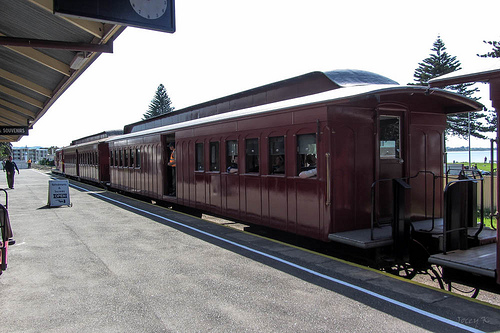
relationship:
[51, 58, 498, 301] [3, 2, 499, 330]
train stopped at station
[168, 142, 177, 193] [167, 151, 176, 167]
man has vest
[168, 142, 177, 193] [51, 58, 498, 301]
man standing on train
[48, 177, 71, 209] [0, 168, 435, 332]
sign sitting on ground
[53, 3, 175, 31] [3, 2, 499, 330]
clock hanging at station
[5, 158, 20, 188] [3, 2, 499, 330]
man walking at station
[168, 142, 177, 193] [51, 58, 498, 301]
man on train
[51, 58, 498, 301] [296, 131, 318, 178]
train has window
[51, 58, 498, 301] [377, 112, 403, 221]
train has door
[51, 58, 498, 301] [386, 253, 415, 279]
train has wheel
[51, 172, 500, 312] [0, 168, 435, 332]
line painted on ground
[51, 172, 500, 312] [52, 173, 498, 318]
line painted on curb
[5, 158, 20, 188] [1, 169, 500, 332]
man walking on sidewalk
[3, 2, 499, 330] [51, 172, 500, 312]
station has line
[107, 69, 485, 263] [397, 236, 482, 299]
car has cable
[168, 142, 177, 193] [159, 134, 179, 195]
man standing at door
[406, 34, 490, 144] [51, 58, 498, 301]
tree over train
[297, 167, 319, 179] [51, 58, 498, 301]
arm out of train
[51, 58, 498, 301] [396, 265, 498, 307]
train sitting on tracks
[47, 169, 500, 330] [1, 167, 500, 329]
shadow on pavement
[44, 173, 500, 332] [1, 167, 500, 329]
paint on pavement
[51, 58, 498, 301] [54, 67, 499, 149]
train has roof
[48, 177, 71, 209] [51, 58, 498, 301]
sign beside train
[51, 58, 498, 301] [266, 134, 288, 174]
train has window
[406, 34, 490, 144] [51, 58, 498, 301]
tree behind train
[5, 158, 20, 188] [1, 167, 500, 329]
man walking on pavement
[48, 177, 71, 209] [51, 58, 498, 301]
sign next to train